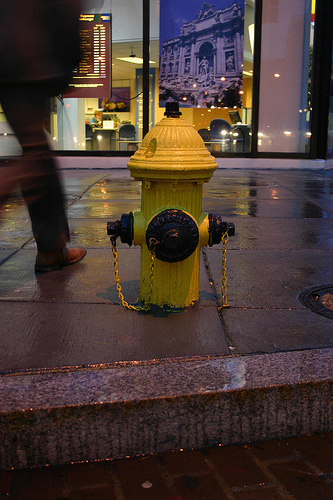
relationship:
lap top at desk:
[225, 107, 242, 124] [225, 106, 248, 146]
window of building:
[41, 0, 257, 155] [2, 0, 330, 168]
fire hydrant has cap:
[97, 89, 241, 309] [161, 98, 183, 120]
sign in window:
[55, 11, 112, 90] [21, 14, 148, 150]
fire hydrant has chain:
[106, 89, 236, 309] [109, 235, 156, 311]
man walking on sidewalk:
[0, 0, 87, 271] [7, 163, 329, 385]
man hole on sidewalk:
[294, 276, 332, 320] [3, 166, 329, 344]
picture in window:
[159, 0, 242, 109] [0, 0, 333, 160]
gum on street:
[138, 480, 154, 489] [5, 429, 330, 495]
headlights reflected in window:
[219, 128, 227, 136] [46, 0, 316, 159]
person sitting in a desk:
[91, 108, 102, 128] [88, 122, 120, 150]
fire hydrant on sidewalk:
[106, 89, 236, 309] [40, 149, 328, 402]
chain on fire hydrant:
[219, 232, 233, 309] [106, 102, 231, 311]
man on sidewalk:
[0, 0, 87, 271] [4, 158, 323, 468]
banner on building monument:
[159, 0, 243, 107] [163, 5, 240, 99]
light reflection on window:
[216, 128, 228, 139] [0, 0, 333, 160]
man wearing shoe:
[0, 0, 87, 271] [33, 246, 87, 272]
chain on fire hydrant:
[219, 232, 230, 309] [106, 89, 236, 309]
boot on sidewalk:
[32, 224, 85, 275] [231, 181, 329, 213]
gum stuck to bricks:
[141, 480, 153, 489] [0, 426, 332, 498]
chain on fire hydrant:
[107, 228, 161, 308] [106, 89, 236, 309]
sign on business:
[55, 11, 112, 90] [91, 20, 103, 71]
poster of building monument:
[157, 1, 242, 110] [158, 0, 243, 104]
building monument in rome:
[158, 0, 243, 104] [156, 9, 247, 105]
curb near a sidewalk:
[1, 347, 332, 468] [3, 166, 329, 344]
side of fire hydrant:
[103, 99, 236, 312] [89, 90, 270, 312]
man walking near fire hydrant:
[0, 0, 87, 271] [106, 102, 231, 311]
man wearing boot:
[0, 0, 87, 271] [33, 243, 88, 277]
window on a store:
[41, 0, 257, 155] [67, 15, 307, 185]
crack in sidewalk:
[201, 243, 213, 308] [192, 318, 268, 358]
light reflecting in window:
[283, 129, 297, 139] [64, 7, 307, 138]